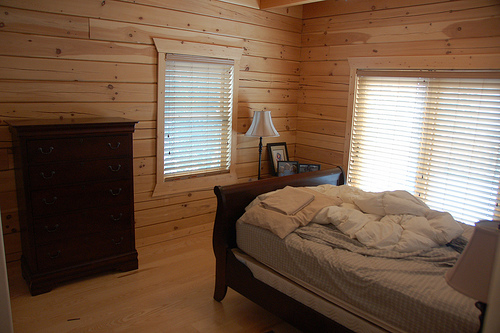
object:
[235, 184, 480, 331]
sheets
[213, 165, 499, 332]
bed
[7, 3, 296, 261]
walls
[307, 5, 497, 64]
walls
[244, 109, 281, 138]
lamp shade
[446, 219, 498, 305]
lamp shade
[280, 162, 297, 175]
pictures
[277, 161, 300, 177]
frames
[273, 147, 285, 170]
pictures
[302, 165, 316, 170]
pictures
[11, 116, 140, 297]
dresser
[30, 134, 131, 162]
drawers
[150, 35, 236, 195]
window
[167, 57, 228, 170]
blinds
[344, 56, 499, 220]
window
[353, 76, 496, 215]
blinds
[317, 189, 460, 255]
comforter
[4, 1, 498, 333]
bedroom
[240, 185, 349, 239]
pillow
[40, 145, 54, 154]
handles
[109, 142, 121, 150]
handles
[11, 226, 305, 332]
floor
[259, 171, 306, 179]
night table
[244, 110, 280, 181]
lamp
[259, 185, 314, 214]
pillow case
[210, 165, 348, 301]
footboard